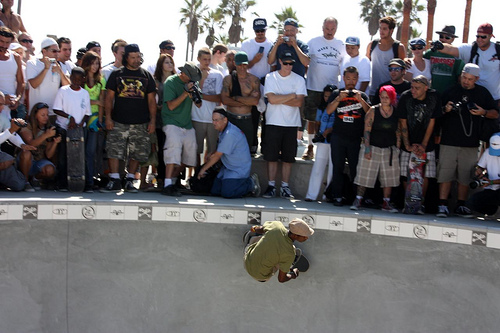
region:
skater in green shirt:
[240, 216, 314, 283]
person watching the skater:
[105, 44, 157, 196]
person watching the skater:
[51, 67, 91, 175]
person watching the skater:
[22, 101, 56, 184]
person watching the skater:
[24, 34, 71, 111]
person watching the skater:
[81, 50, 105, 185]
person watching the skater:
[261, 47, 305, 198]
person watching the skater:
[326, 67, 368, 202]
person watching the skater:
[355, 82, 397, 203]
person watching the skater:
[397, 75, 439, 205]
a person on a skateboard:
[225, 210, 321, 280]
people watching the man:
[10, 21, 496, 216]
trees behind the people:
[175, 2, 250, 52]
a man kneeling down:
[205, 110, 261, 196]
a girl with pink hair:
[365, 81, 400, 206]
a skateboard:
[410, 145, 422, 206]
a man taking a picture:
[277, 20, 297, 51]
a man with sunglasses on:
[271, 50, 301, 180]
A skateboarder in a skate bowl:
[236, 207, 323, 289]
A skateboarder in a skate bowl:
[235, 213, 322, 290]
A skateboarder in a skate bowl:
[241, 216, 321, 288]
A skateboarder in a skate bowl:
[230, 214, 324, 290]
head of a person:
[120, 38, 154, 70]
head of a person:
[152, 52, 176, 96]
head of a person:
[206, 96, 240, 136]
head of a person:
[280, 185, 322, 240]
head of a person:
[367, 75, 392, 113]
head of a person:
[405, 69, 440, 101]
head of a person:
[382, 46, 416, 86]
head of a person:
[447, 55, 485, 100]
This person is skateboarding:
[229, 195, 316, 288]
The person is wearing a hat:
[277, 210, 318, 244]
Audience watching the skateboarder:
[5, 3, 498, 200]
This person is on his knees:
[196, 107, 258, 200]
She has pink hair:
[360, 79, 402, 195]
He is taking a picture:
[266, 10, 311, 70]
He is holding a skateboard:
[57, 60, 94, 195]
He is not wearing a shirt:
[221, 54, 258, 118]